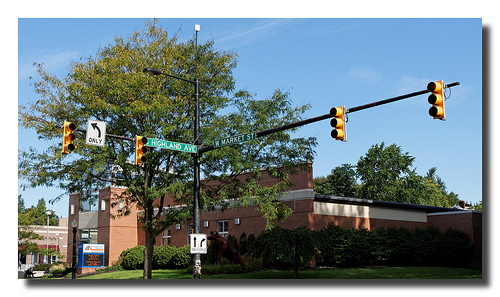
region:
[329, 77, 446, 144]
Two yellow traffic light fixtures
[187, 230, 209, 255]
White square traffic sign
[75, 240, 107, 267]
Blue LED building sign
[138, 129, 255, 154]
Two green street signs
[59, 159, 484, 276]
Large brown brick building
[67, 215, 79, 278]
Black metal pole street lamp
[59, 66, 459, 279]
Black poles holding traffic light fixtures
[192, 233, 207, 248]
Two black directional arrows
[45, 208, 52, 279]
Silver parking lot lamp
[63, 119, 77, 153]
A three color traffic light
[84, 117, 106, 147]
A turn left only sign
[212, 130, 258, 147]
A green street sign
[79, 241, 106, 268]
A digital school sign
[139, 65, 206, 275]
A street light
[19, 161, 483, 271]
A school building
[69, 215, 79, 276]
A black street lamp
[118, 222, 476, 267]
A line of shrubs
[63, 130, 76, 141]
A yellow traffic light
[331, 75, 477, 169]
the traffic lights are yellow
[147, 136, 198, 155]
the street sign is green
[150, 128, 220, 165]
the street is highland avanue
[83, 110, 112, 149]
the sign is white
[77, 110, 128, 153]
the text is black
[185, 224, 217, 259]
two arrows on the sign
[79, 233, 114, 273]
the sign is electronic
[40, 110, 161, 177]
Two traffic lights on a metal pole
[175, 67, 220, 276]
the pole is black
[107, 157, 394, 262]
building is made of brick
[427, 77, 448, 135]
yellow traffic signal on pole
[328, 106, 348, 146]
yellow traffic signal in the air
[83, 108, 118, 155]
white and black turn left sign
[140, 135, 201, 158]
green and white street sign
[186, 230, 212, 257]
white and black sign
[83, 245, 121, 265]
sign outside of building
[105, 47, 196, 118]
trees in front of building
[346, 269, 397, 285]
green grass on the ground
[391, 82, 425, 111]
cloud in the sky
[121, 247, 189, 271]
bushes near the building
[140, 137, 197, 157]
a sign with the word Highland Ave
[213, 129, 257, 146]
a sign with the word W Market ST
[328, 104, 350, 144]
a stop light on a pole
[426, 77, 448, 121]
a stop light on a pole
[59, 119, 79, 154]
a stop light on a pole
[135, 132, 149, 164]
a stop light on a pole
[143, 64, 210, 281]
a metal light post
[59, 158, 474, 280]
a light brown building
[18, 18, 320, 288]
a green tree on the sidewalk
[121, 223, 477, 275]
a row of green shrubs